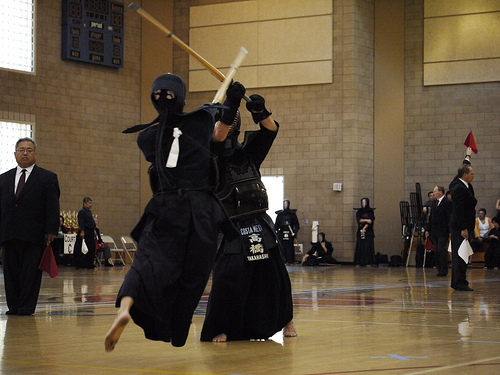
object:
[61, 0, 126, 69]
scoreboard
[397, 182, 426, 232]
gates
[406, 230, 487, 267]
bleachers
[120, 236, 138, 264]
chair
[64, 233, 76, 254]
table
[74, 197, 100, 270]
man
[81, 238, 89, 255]
hanky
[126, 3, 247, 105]
bats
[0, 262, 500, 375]
floor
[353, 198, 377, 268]
competitor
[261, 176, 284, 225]
door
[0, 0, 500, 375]
wall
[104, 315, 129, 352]
foot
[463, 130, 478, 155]
cloth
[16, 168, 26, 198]
tie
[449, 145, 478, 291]
man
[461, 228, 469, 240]
hands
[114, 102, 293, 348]
robes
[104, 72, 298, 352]
fighters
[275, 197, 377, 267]
participants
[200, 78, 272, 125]
gloves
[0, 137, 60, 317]
man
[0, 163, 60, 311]
suit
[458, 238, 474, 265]
cloth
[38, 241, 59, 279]
cloth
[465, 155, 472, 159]
wristwatch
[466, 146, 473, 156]
hand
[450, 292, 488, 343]
reflection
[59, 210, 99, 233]
trophies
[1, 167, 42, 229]
man's chest